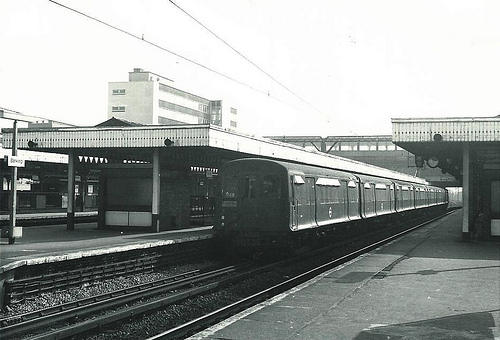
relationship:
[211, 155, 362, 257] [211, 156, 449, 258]
front car of train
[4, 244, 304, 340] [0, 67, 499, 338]
tracks at station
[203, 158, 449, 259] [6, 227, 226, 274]
train on platform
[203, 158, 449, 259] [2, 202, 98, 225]
train on platform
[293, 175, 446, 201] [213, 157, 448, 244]
windows on train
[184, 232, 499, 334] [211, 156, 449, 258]
platform on left of train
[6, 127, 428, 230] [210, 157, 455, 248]
covered area on platform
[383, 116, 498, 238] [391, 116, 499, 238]
covered area on platform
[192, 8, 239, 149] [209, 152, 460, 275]
cables are above train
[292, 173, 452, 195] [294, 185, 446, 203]
awning over windows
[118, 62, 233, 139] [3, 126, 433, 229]
rise behind depot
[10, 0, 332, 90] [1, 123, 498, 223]
wires are above roof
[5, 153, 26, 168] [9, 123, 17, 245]
sign on box/pole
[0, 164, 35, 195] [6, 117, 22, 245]
box on pole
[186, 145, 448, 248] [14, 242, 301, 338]
train on track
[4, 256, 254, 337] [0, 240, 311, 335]
tracks are on ground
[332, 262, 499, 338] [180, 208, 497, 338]
casting on ground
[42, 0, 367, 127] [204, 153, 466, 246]
powerlines are above train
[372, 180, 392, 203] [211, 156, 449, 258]
windows are on train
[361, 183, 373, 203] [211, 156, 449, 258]
windows are on train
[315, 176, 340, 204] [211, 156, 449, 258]
windows are on train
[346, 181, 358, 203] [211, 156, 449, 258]
windows are on train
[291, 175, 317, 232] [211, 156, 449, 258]
windows are on train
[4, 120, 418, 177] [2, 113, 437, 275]
roof on station